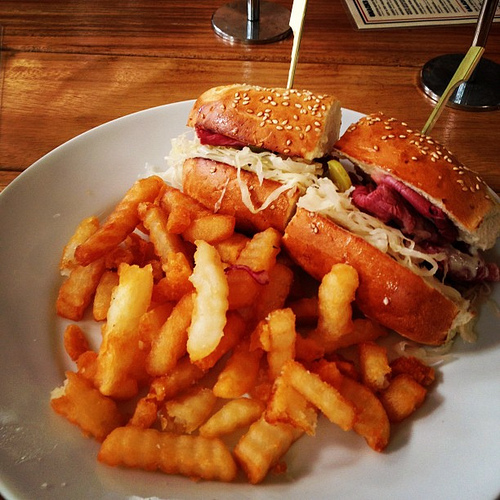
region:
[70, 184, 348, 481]
a pile of french fries on a plate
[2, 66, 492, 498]
a white plate holding food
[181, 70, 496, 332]
a sandwich with beef and sauerkraut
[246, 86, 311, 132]
sesame seeds on a piece of bread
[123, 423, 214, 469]
ripple shape frenchfry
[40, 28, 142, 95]
the grain in wood boards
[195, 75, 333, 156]
the top of a sandwhich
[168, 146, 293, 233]
the bottom of a sandwich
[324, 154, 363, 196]
a pickle in a sandwich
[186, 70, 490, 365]
a sandwich that is cut in half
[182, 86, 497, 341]
reuben sandwich cut in half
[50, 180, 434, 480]
french fries on a plate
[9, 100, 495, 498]
a white plate with a sandwich and fries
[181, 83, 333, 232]
half of the sandwich with the white toothpick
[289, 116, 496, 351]
half of the sandwich with the green toothpick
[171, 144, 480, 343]
coleslaw on the sandwich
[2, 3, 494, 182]
a wooden table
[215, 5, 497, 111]
bases of two metal stands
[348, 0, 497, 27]
a paper menu on the table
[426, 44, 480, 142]
the green toothpick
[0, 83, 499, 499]
A reuben sandwich and french fries.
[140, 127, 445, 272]
sauerkraut on the sandwich.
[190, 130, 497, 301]
Roast beef on the sandwich.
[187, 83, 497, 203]
Sesame seeds on top of the bun.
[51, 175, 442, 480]
Crinkle french fries on top of the plate.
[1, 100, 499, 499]
A white plate.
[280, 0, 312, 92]
A white toothpick poked into the bun.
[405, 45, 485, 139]
Green toothpick in the bun.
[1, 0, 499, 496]
White plate sitting on top of a wooden table.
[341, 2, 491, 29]
A Menu sitting on top of the table.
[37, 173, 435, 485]
fries on the plate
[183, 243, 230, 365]
this fry is white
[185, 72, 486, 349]
a reuben sandwich on the plate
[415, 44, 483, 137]
the stick is green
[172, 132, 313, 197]
sauerkraut in the sandwich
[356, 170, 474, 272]
corned beef in the sandwich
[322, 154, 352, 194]
a pickle in the sandwich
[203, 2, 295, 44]
a silver base on the table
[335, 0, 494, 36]
a menu on the table